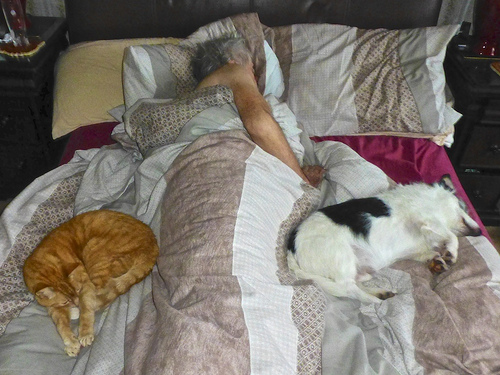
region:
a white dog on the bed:
[289, 193, 478, 299]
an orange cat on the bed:
[30, 208, 157, 355]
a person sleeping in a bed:
[182, 18, 314, 354]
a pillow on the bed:
[51, 40, 181, 126]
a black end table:
[440, 48, 497, 199]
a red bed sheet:
[339, 133, 462, 193]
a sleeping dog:
[299, 173, 483, 295]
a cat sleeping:
[28, 210, 162, 354]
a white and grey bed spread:
[141, 129, 292, 368]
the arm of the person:
[232, 72, 317, 174]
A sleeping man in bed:
[158, 16, 323, 353]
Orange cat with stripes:
[21, 190, 184, 370]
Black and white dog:
[279, 146, 479, 340]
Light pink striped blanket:
[23, 123, 486, 372]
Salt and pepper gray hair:
[153, 28, 269, 73]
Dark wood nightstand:
[16, 11, 72, 147]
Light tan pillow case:
[44, 28, 252, 150]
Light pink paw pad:
[414, 248, 457, 283]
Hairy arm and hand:
[237, 69, 337, 198]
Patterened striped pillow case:
[263, 16, 468, 150]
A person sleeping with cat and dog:
[23, 13, 495, 368]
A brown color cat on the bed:
[23, 191, 155, 340]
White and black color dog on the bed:
[298, 169, 498, 309]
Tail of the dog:
[282, 252, 339, 300]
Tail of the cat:
[105, 251, 158, 301]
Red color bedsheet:
[372, 138, 424, 161]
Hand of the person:
[235, 68, 322, 178]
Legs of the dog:
[421, 220, 464, 269]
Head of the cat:
[29, 274, 96, 312]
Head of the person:
[192, 34, 257, 70]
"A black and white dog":
[281, 169, 494, 312]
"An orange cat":
[18, 201, 184, 359]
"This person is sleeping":
[158, 3, 301, 373]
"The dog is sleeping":
[286, 163, 498, 301]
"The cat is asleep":
[19, 206, 169, 371]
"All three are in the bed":
[5, 2, 495, 374]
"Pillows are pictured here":
[32, 18, 482, 146]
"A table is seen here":
[0, 1, 70, 161]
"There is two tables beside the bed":
[2, 3, 498, 210]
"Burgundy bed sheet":
[52, 122, 492, 231]